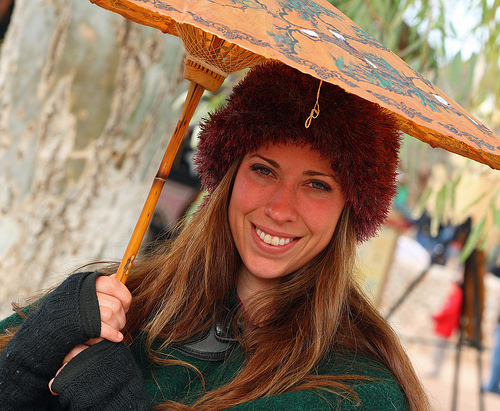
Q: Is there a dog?
A: No, there are no dogs.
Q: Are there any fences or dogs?
A: No, there are no dogs or fences.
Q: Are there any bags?
A: No, there are no bags.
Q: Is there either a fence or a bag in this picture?
A: No, there are no bags or fences.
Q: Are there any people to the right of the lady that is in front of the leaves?
A: Yes, there is a person to the right of the lady.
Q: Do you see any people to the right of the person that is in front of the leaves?
A: Yes, there is a person to the right of the lady.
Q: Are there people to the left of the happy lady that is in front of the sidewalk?
A: No, the person is to the right of the lady.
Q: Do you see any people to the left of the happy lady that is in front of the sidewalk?
A: No, the person is to the right of the lady.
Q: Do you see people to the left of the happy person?
A: No, the person is to the right of the lady.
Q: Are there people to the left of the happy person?
A: No, the person is to the right of the lady.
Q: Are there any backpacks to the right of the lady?
A: No, there is a person to the right of the lady.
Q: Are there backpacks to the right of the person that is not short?
A: No, there is a person to the right of the lady.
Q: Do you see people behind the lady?
A: Yes, there is a person behind the lady.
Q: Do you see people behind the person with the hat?
A: Yes, there is a person behind the lady.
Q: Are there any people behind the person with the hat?
A: Yes, there is a person behind the lady.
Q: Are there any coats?
A: Yes, there is a coat.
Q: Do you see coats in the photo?
A: Yes, there is a coat.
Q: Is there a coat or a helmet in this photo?
A: Yes, there is a coat.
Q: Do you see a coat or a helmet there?
A: Yes, there is a coat.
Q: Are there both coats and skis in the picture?
A: No, there is a coat but no skis.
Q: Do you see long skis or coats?
A: Yes, there is a long coat.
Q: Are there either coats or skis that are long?
A: Yes, the coat is long.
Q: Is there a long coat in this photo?
A: Yes, there is a long coat.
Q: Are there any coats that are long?
A: Yes, there is a coat that is long.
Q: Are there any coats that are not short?
A: Yes, there is a long coat.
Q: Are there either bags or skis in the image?
A: No, there are no bags or skis.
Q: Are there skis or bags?
A: No, there are no bags or skis.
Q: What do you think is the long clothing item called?
A: The clothing item is a coat.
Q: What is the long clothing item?
A: The clothing item is a coat.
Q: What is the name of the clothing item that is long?
A: The clothing item is a coat.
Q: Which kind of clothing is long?
A: The clothing is a coat.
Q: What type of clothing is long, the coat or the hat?
A: The coat is long.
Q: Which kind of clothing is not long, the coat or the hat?
A: The hat is not long.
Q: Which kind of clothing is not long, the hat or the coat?
A: The hat is not long.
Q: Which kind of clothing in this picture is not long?
A: The clothing is a hat.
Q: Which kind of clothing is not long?
A: The clothing is a hat.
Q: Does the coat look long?
A: Yes, the coat is long.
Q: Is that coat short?
A: No, the coat is long.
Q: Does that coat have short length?
A: No, the coat is long.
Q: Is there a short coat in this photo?
A: No, there is a coat but it is long.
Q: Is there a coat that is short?
A: No, there is a coat but it is long.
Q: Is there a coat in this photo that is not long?
A: No, there is a coat but it is long.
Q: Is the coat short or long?
A: The coat is long.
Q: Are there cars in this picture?
A: No, there are no cars.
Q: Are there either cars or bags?
A: No, there are no cars or bags.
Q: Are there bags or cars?
A: No, there are no cars or bags.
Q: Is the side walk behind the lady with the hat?
A: Yes, the side walk is behind the lady.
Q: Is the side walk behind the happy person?
A: Yes, the side walk is behind the lady.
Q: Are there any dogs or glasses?
A: No, there are no glasses or dogs.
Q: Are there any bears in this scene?
A: No, there are no bears.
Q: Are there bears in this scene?
A: No, there are no bears.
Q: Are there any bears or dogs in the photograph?
A: No, there are no bears or dogs.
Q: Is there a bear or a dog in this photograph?
A: No, there are no bears or dogs.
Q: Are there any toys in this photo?
A: No, there are no toys.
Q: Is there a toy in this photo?
A: No, there are no toys.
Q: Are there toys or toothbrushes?
A: No, there are no toys or toothbrushes.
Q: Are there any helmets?
A: No, there are no helmets.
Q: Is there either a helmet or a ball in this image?
A: No, there are no helmets or balls.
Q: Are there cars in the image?
A: No, there are no cars.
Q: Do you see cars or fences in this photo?
A: No, there are no cars or fences.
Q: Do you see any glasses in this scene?
A: No, there are no glasses.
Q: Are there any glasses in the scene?
A: No, there are no glasses.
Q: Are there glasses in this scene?
A: No, there are no glasses.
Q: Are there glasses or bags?
A: No, there are no glasses or bags.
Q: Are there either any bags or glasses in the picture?
A: No, there are no glasses or bags.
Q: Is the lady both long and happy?
A: Yes, the lady is long and happy.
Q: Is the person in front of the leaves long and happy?
A: Yes, the lady is long and happy.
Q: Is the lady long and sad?
A: No, the lady is long but happy.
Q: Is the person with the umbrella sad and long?
A: No, the lady is long but happy.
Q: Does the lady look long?
A: Yes, the lady is long.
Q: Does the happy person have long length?
A: Yes, the lady is long.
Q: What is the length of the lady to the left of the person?
A: The lady is long.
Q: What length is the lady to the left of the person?
A: The lady is long.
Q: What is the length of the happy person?
A: The lady is long.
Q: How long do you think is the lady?
A: The lady is long.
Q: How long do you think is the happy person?
A: The lady is long.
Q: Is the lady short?
A: No, the lady is long.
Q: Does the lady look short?
A: No, the lady is long.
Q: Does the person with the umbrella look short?
A: No, the lady is long.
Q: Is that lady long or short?
A: The lady is long.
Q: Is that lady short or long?
A: The lady is long.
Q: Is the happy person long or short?
A: The lady is long.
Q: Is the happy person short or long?
A: The lady is long.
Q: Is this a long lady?
A: Yes, this is a long lady.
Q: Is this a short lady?
A: No, this is a long lady.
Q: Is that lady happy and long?
A: Yes, the lady is happy and long.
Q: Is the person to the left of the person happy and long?
A: Yes, the lady is happy and long.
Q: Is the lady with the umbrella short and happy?
A: No, the lady is happy but long.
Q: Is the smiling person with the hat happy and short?
A: No, the lady is happy but long.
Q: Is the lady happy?
A: Yes, the lady is happy.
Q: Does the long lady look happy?
A: Yes, the lady is happy.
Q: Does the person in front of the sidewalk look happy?
A: Yes, the lady is happy.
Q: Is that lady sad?
A: No, the lady is happy.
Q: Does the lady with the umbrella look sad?
A: No, the lady is happy.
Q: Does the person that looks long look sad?
A: No, the lady is happy.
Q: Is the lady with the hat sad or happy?
A: The lady is happy.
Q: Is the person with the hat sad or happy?
A: The lady is happy.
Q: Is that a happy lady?
A: Yes, that is a happy lady.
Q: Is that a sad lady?
A: No, that is a happy lady.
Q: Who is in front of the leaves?
A: The lady is in front of the leaves.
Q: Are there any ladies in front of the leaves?
A: Yes, there is a lady in front of the leaves.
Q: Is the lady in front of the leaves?
A: Yes, the lady is in front of the leaves.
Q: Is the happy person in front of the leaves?
A: Yes, the lady is in front of the leaves.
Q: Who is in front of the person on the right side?
A: The lady is in front of the person.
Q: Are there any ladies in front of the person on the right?
A: Yes, there is a lady in front of the person.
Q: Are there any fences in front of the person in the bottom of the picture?
A: No, there is a lady in front of the person.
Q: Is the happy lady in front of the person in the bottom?
A: Yes, the lady is in front of the person.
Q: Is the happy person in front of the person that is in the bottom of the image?
A: Yes, the lady is in front of the person.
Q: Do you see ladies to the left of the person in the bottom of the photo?
A: Yes, there is a lady to the left of the person.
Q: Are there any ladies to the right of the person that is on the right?
A: No, the lady is to the left of the person.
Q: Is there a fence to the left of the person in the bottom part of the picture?
A: No, there is a lady to the left of the person.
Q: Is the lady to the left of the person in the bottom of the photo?
A: Yes, the lady is to the left of the person.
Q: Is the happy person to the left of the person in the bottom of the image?
A: Yes, the lady is to the left of the person.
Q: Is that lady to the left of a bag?
A: No, the lady is to the left of the person.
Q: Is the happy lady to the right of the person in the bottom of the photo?
A: No, the lady is to the left of the person.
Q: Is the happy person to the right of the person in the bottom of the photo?
A: No, the lady is to the left of the person.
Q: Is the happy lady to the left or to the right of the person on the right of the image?
A: The lady is to the left of the person.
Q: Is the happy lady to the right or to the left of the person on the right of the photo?
A: The lady is to the left of the person.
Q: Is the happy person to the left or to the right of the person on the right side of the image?
A: The lady is to the left of the person.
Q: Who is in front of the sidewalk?
A: The lady is in front of the sidewalk.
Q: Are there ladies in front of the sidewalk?
A: Yes, there is a lady in front of the sidewalk.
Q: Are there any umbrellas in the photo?
A: Yes, there is an umbrella.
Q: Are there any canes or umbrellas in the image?
A: Yes, there is an umbrella.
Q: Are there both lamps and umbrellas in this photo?
A: No, there is an umbrella but no lamps.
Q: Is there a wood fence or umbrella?
A: Yes, there is a wood umbrella.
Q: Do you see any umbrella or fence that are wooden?
A: Yes, the umbrella is wooden.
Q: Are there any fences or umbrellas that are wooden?
A: Yes, the umbrella is wooden.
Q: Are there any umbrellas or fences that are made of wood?
A: Yes, the umbrella is made of wood.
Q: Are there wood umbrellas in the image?
A: Yes, there is a wood umbrella.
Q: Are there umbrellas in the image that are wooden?
A: Yes, there is an umbrella that is wooden.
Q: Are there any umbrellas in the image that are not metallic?
A: Yes, there is a wooden umbrella.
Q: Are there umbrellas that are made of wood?
A: Yes, there is an umbrella that is made of wood.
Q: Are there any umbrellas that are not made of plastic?
A: Yes, there is an umbrella that is made of wood.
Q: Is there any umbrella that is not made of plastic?
A: Yes, there is an umbrella that is made of wood.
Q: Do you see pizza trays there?
A: No, there are no pizza trays.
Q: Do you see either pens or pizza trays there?
A: No, there are no pizza trays or pens.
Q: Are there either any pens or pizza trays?
A: No, there are no pizza trays or pens.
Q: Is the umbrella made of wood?
A: Yes, the umbrella is made of wood.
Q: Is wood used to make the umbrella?
A: Yes, the umbrella is made of wood.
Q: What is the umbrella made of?
A: The umbrella is made of wood.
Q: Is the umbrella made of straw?
A: No, the umbrella is made of wood.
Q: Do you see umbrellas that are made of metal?
A: No, there is an umbrella but it is made of wood.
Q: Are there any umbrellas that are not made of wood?
A: No, there is an umbrella but it is made of wood.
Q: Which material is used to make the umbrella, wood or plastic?
A: The umbrella is made of wood.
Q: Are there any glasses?
A: No, there are no glasses.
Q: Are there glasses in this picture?
A: No, there are no glasses.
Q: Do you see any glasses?
A: No, there are no glasses.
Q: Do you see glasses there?
A: No, there are no glasses.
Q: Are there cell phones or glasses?
A: No, there are no glasses or cell phones.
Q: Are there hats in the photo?
A: Yes, there is a hat.